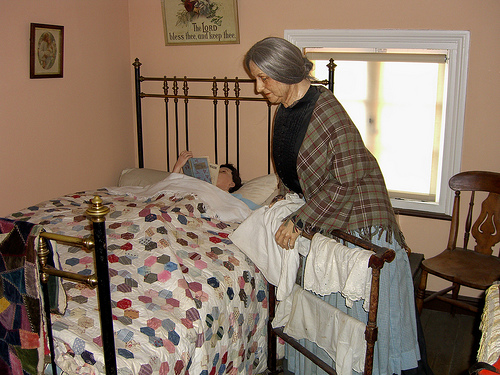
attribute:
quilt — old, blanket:
[0, 171, 272, 373]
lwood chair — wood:
[420, 173, 498, 279]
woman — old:
[221, 33, 416, 255]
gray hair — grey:
[241, 34, 312, 87]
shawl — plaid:
[296, 115, 389, 235]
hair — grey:
[242, 37, 312, 81]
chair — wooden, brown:
[412, 168, 498, 369]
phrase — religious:
[148, 0, 248, 46]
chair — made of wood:
[410, 166, 498, 326]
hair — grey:
[265, 41, 298, 65]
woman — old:
[236, 35, 423, 371]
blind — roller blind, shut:
[304, 46, 448, 204]